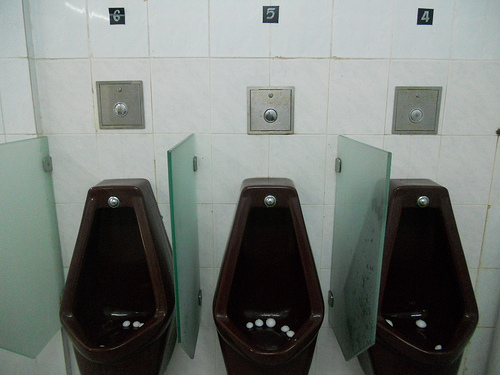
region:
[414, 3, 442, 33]
number 4 on the wall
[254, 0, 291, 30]
number 5 on the wall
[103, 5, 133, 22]
number 6 on the wall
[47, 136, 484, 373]
three urinals on a wall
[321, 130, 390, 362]
glass divider between the urinals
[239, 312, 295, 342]
white balls in the urinals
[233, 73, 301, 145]
flush button on the wall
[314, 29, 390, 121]
dirty white tiled wall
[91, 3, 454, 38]
numbers above the urinals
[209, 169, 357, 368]
brown urinal in the middle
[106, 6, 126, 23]
plaque with the number 6 on it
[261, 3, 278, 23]
plaque with a number 5 on it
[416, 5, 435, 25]
plaque with a number 4 on it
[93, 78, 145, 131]
silver panel with the flusher button on it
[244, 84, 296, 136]
silver panel with the flusher button on it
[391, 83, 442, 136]
silver panel with the flusher button on it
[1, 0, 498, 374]
white tile wall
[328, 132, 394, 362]
frosted glass partition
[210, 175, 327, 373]
dark brown urinal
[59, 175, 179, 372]
dark brown urinal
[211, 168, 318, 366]
The urinal in the middle is brown.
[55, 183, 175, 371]
The urinal on the left is brown.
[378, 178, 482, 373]
The urinal on the right is brown.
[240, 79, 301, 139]
The wall fixture in the middle is silver.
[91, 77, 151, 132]
The wall fixture on the left is silver.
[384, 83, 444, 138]
The wall fixture on the right is silver.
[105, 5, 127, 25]
The number on the left is six.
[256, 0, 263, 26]
The number in the middle is five.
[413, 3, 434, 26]
The number on the right is four.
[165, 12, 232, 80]
The bathroom wall is white.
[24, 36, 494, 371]
A number of urinals in the bathroom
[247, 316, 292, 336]
Small white urinal cakes in the urinals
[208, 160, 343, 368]
The urinal appears to be made of wood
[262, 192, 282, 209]
A small grey knob on the brown urinal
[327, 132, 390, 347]
A translucent glass divider between urinals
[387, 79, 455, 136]
A small grey tile above the urinal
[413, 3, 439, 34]
The number of the below urinal is 4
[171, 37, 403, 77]
White tile on the bathroom wall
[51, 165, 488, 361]
Three identical wooden urinals in a bathroom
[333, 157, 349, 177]
A small grey hinge on the urinal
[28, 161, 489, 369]
Three brown urinals in bathroom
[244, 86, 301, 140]
Silver flusher above urinal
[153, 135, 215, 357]
Glass separator for privacy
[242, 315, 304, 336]
Cleaning tablets in bowl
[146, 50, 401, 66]
dirty grout on wall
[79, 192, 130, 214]
Silver knob on top of urinal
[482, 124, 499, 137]
Black spot on wall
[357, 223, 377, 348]
Water splash on glass separator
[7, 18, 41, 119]
Mirror on the wall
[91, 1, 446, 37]
Numbers on the wall